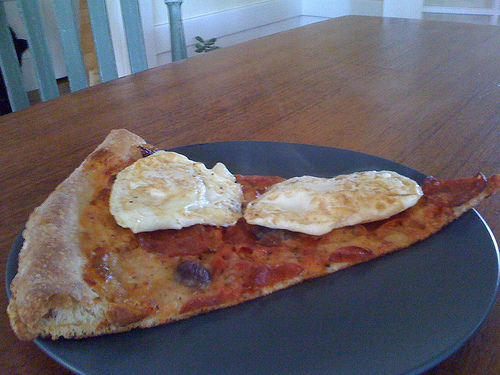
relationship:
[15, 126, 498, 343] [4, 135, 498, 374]
pizza on plate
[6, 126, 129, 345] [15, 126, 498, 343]
crust of pizza